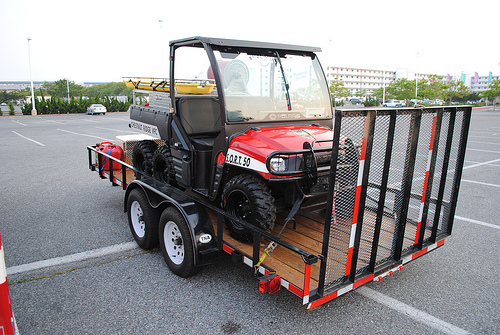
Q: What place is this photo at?
A: It is at the parking lot.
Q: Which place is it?
A: It is a parking lot.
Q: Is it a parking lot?
A: Yes, it is a parking lot.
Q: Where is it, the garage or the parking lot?
A: It is the parking lot.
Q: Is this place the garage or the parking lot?
A: It is the parking lot.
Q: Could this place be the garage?
A: No, it is the parking lot.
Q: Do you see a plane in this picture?
A: No, there are no airplanes.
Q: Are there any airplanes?
A: No, there are no airplanes.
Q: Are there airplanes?
A: No, there are no airplanes.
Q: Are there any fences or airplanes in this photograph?
A: No, there are no airplanes or fences.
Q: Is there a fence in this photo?
A: No, there are no fences.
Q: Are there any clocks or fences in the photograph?
A: No, there are no fences or clocks.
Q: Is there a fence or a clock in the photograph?
A: No, there are no fences or clocks.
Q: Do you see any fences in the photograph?
A: No, there are no fences.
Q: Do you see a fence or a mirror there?
A: No, there are no fences or mirrors.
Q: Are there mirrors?
A: No, there are no mirrors.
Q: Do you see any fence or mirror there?
A: No, there are no mirrors or fences.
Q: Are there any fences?
A: No, there are no fences.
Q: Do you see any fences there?
A: No, there are no fences.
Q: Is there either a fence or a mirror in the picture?
A: No, there are no fences or mirrors.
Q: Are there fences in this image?
A: No, there are no fences.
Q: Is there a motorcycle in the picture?
A: No, there are no motorcycles.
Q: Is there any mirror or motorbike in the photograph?
A: No, there are no motorcycles or mirrors.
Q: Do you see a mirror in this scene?
A: No, there are no mirrors.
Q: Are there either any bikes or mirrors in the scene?
A: No, there are no mirrors or bikes.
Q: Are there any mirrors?
A: No, there are no mirrors.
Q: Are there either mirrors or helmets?
A: No, there are no mirrors or helmets.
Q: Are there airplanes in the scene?
A: No, there are no airplanes.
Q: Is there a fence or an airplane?
A: No, there are no airplanes or fences.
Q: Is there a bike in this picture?
A: No, there are no bikes.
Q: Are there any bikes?
A: No, there are no bikes.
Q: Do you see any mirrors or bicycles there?
A: No, there are no bicycles or mirrors.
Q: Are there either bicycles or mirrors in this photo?
A: No, there are no bicycles or mirrors.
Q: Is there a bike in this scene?
A: No, there are no bikes.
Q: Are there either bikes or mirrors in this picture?
A: No, there are no bikes or mirrors.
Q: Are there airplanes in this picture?
A: No, there are no airplanes.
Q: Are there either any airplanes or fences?
A: No, there are no airplanes or fences.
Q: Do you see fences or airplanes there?
A: No, there are no airplanes or fences.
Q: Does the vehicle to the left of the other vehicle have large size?
A: Yes, the vehicle is large.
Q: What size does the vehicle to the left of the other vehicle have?
A: The vehicle has large size.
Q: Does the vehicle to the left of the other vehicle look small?
A: No, the vehicle is large.